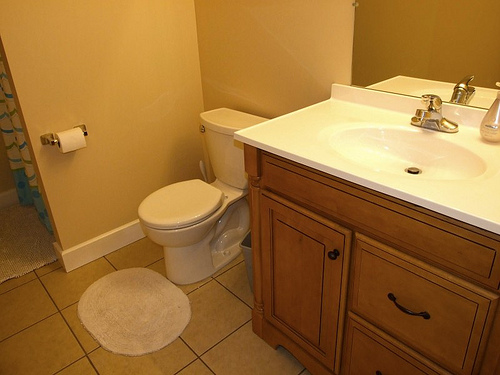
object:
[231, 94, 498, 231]
sink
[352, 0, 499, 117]
mirror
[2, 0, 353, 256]
wall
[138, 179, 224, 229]
toilet cover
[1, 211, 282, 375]
floor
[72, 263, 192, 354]
mat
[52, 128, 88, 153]
toilet paper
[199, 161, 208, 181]
toilet brush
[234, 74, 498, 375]
counter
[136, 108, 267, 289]
toilet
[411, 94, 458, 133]
faucet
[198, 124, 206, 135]
mechanism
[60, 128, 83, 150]
roll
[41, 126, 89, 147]
holder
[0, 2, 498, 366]
area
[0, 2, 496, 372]
bathroom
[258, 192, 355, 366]
door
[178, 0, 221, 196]
corner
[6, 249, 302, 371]
tile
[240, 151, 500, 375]
cabinet